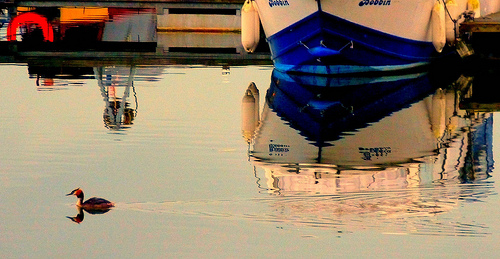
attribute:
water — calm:
[3, 58, 499, 257]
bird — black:
[66, 187, 114, 215]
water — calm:
[152, 113, 258, 188]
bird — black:
[45, 170, 122, 224]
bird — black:
[61, 184, 113, 215]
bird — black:
[42, 153, 162, 243]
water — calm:
[33, 83, 185, 142]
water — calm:
[16, 153, 46, 257]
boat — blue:
[254, 2, 441, 82]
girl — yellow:
[122, 108, 134, 126]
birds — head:
[54, 186, 116, 215]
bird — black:
[62, 182, 122, 215]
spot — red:
[69, 185, 84, 195]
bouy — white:
[240, 0, 256, 52]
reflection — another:
[90, 62, 140, 133]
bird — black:
[64, 186, 117, 208]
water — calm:
[247, 170, 452, 229]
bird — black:
[46, 162, 136, 247]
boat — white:
[237, 0, 469, 17]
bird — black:
[52, 180, 129, 229]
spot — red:
[73, 186, 81, 196]